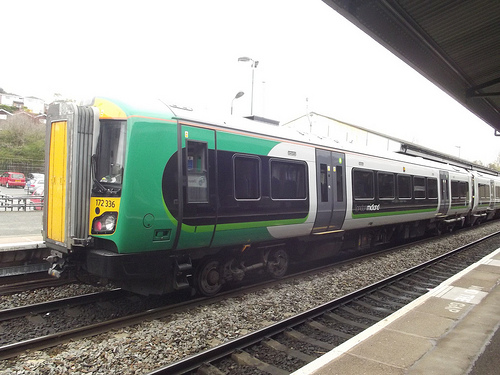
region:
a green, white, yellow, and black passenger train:
[38, 88, 488, 286]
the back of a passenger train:
[43, 102, 140, 287]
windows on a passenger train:
[227, 147, 312, 212]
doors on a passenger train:
[311, 143, 347, 232]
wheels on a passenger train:
[186, 250, 293, 298]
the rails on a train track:
[124, 285, 437, 373]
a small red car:
[0, 163, 27, 193]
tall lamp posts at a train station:
[228, 48, 276, 120]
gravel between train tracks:
[86, 310, 356, 361]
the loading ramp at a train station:
[376, 254, 491, 370]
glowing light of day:
[0, 2, 497, 173]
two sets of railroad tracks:
[0, 291, 323, 371]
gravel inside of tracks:
[2, 294, 144, 345]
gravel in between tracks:
[6, 223, 497, 373]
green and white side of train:
[121, 110, 498, 251]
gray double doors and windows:
[315, 148, 346, 233]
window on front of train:
[94, 117, 126, 194]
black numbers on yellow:
[92, 197, 119, 207]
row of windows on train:
[350, 166, 439, 201]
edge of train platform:
[294, 250, 499, 374]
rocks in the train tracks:
[123, 310, 190, 360]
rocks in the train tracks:
[251, 298, 314, 348]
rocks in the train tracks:
[210, 276, 286, 355]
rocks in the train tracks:
[251, 278, 312, 301]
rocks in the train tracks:
[219, 303, 284, 338]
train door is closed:
[291, 133, 367, 235]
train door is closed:
[422, 155, 467, 233]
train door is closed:
[308, 153, 356, 252]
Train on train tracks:
[37, 90, 498, 299]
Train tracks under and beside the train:
[0, 207, 498, 374]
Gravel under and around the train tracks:
[0, 199, 497, 374]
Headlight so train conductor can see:
[90, 210, 117, 234]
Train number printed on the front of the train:
[93, 195, 120, 208]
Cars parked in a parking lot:
[0, 165, 45, 213]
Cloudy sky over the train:
[0, 0, 499, 176]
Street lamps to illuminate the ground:
[222, 47, 282, 122]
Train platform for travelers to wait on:
[310, 240, 497, 372]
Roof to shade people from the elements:
[324, 0, 498, 132]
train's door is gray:
[286, 115, 348, 268]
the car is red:
[0, 163, 35, 202]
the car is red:
[0, 163, 70, 214]